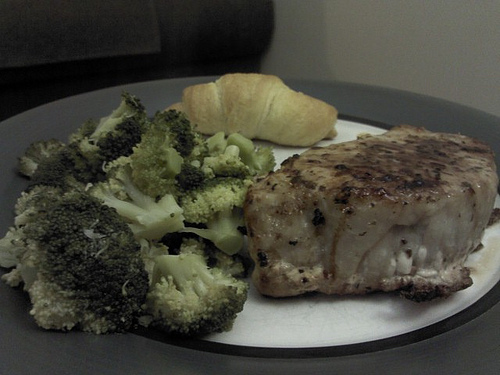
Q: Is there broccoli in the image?
A: Yes, there is broccoli.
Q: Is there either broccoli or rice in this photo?
A: Yes, there is broccoli.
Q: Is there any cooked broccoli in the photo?
A: Yes, there is cooked broccoli.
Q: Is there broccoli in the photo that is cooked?
A: Yes, there is broccoli that is cooked.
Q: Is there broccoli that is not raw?
A: Yes, there is cooked broccoli.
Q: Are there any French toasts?
A: No, there are no French toasts.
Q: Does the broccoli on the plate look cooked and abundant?
A: Yes, the broccoli is cooked and abundant.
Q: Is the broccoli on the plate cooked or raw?
A: The broccoli is cooked.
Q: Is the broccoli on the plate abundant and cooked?
A: Yes, the broccoli is abundant and cooked.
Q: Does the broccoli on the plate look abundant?
A: Yes, the broccoli is abundant.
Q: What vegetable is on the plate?
A: The vegetable is broccoli.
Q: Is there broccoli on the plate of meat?
A: Yes, there is broccoli on the plate.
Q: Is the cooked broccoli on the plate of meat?
A: Yes, the broccoli is on the plate.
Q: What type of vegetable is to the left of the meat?
A: The vegetable is broccoli.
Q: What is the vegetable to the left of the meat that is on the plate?
A: The vegetable is broccoli.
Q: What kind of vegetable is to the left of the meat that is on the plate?
A: The vegetable is broccoli.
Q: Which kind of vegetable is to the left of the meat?
A: The vegetable is broccoli.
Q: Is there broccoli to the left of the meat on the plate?
A: Yes, there is broccoli to the left of the meat.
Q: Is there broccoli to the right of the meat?
A: No, the broccoli is to the left of the meat.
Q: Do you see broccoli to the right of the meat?
A: No, the broccoli is to the left of the meat.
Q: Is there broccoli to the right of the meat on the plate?
A: No, the broccoli is to the left of the meat.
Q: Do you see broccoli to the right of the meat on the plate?
A: No, the broccoli is to the left of the meat.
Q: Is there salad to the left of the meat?
A: No, there is broccoli to the left of the meat.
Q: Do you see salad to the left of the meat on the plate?
A: No, there is broccoli to the left of the meat.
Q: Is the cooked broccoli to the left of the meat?
A: Yes, the broccoli is to the left of the meat.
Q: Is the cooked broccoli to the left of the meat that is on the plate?
A: Yes, the broccoli is to the left of the meat.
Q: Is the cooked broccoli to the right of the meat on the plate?
A: No, the broccoli is to the left of the meat.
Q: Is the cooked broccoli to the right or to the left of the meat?
A: The broccoli is to the left of the meat.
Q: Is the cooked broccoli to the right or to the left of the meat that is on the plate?
A: The broccoli is to the left of the meat.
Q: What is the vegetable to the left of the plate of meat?
A: The vegetable is broccoli.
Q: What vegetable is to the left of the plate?
A: The vegetable is broccoli.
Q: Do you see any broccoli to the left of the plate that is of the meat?
A: Yes, there is broccoli to the left of the plate.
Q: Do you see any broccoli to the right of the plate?
A: No, the broccoli is to the left of the plate.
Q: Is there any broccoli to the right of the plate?
A: No, the broccoli is to the left of the plate.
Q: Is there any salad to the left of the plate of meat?
A: No, there is broccoli to the left of the plate.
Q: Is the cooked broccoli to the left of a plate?
A: Yes, the broccoli is to the left of a plate.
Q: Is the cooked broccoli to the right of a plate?
A: No, the broccoli is to the left of a plate.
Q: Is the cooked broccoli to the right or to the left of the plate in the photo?
A: The broccoli is to the left of the plate.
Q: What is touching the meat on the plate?
A: The broccoli is touching the meat.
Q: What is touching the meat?
A: The broccoli is touching the meat.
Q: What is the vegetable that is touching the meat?
A: The vegetable is broccoli.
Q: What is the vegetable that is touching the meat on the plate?
A: The vegetable is broccoli.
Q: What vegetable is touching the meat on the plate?
A: The vegetable is broccoli.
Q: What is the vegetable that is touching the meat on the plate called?
A: The vegetable is broccoli.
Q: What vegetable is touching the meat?
A: The vegetable is broccoli.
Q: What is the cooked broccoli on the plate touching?
A: The broccoli is touching the meat.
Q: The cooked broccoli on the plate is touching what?
A: The broccoli is touching the meat.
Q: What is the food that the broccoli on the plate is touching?
A: The food is meat.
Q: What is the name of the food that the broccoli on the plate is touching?
A: The food is meat.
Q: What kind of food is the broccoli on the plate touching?
A: The broccoli is touching the meat.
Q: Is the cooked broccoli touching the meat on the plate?
A: Yes, the broccoli is touching the meat.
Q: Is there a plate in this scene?
A: Yes, there is a plate.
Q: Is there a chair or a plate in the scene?
A: Yes, there is a plate.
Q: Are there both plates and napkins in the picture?
A: No, there is a plate but no napkins.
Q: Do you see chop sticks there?
A: No, there are no chop sticks.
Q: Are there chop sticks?
A: No, there are no chop sticks.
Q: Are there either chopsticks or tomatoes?
A: No, there are no chopsticks or tomatoes.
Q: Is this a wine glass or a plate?
A: This is a plate.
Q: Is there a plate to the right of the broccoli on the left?
A: Yes, there is a plate to the right of the broccoli.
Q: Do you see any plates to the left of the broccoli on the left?
A: No, the plate is to the right of the broccoli.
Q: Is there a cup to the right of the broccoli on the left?
A: No, there is a plate to the right of the broccoli.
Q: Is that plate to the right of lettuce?
A: No, the plate is to the right of the broccoli.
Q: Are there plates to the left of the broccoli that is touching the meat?
A: No, the plate is to the right of the broccoli.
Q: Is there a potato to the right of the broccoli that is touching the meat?
A: No, there is a plate to the right of the broccoli.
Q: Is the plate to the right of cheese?
A: No, the plate is to the right of the broccoli.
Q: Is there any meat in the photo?
A: Yes, there is meat.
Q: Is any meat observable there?
A: Yes, there is meat.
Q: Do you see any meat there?
A: Yes, there is meat.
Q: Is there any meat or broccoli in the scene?
A: Yes, there is meat.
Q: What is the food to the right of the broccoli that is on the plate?
A: The food is meat.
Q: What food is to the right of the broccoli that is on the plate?
A: The food is meat.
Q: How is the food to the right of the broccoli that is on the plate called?
A: The food is meat.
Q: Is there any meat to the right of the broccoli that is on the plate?
A: Yes, there is meat to the right of the broccoli.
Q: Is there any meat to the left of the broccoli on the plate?
A: No, the meat is to the right of the broccoli.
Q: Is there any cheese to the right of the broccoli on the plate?
A: No, there is meat to the right of the broccoli.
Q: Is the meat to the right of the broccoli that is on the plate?
A: Yes, the meat is to the right of the broccoli.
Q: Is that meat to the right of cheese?
A: No, the meat is to the right of the broccoli.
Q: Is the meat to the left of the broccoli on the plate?
A: No, the meat is to the right of the broccoli.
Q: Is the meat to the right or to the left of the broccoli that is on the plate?
A: The meat is to the right of the broccoli.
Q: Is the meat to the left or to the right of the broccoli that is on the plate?
A: The meat is to the right of the broccoli.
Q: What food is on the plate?
A: The food is meat.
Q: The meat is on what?
A: The meat is on the plate.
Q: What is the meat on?
A: The meat is on the plate.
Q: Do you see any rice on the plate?
A: No, there is meat on the plate.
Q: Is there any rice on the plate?
A: No, there is meat on the plate.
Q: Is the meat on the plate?
A: Yes, the meat is on the plate.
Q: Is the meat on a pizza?
A: No, the meat is on the plate.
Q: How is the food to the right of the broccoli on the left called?
A: The food is meat.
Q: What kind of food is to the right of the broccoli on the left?
A: The food is meat.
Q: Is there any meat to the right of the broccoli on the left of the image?
A: Yes, there is meat to the right of the broccoli.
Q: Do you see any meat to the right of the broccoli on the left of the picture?
A: Yes, there is meat to the right of the broccoli.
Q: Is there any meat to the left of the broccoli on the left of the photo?
A: No, the meat is to the right of the broccoli.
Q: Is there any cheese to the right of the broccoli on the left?
A: No, there is meat to the right of the broccoli.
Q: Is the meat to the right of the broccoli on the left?
A: Yes, the meat is to the right of the broccoli.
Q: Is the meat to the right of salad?
A: No, the meat is to the right of the broccoli.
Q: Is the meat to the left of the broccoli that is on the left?
A: No, the meat is to the right of the broccoli.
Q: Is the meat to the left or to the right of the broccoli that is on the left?
A: The meat is to the right of the broccoli.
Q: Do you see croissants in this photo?
A: Yes, there is a croissant.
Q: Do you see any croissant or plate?
A: Yes, there is a croissant.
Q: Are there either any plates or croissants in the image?
A: Yes, there is a croissant.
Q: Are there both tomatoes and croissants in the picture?
A: No, there is a croissant but no tomatoes.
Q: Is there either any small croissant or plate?
A: Yes, there is a small croissant.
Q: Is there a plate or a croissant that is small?
A: Yes, the croissant is small.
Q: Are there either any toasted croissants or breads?
A: Yes, there is a toasted croissant.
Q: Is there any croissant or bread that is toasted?
A: Yes, the croissant is toasted.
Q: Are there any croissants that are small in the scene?
A: Yes, there is a small croissant.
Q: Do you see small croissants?
A: Yes, there is a small croissant.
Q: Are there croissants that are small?
A: Yes, there is a croissant that is small.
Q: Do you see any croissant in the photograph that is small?
A: Yes, there is a croissant that is small.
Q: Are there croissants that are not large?
A: Yes, there is a small croissant.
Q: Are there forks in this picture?
A: No, there are no forks.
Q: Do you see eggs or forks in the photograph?
A: No, there are no forks or eggs.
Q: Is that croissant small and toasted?
A: Yes, the croissant is small and toasted.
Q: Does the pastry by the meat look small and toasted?
A: Yes, the croissant is small and toasted.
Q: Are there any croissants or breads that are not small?
A: No, there is a croissant but it is small.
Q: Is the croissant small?
A: Yes, the croissant is small.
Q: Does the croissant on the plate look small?
A: Yes, the croissant is small.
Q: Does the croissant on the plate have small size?
A: Yes, the croissant is small.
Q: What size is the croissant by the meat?
A: The croissant is small.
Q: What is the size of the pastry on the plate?
A: The croissant is small.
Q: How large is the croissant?
A: The croissant is small.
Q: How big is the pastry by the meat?
A: The croissant is small.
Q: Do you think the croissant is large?
A: No, the croissant is small.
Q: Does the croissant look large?
A: No, the croissant is small.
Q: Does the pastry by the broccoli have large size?
A: No, the croissant is small.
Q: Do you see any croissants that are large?
A: No, there is a croissant but it is small.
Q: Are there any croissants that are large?
A: No, there is a croissant but it is small.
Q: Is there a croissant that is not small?
A: No, there is a croissant but it is small.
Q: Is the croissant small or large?
A: The croissant is small.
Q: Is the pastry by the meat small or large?
A: The croissant is small.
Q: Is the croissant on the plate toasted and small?
A: Yes, the croissant is toasted and small.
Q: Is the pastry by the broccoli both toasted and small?
A: Yes, the croissant is toasted and small.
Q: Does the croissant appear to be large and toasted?
A: No, the croissant is toasted but small.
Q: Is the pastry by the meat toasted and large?
A: No, the croissant is toasted but small.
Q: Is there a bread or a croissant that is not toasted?
A: No, there is a croissant but it is toasted.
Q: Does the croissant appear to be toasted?
A: Yes, the croissant is toasted.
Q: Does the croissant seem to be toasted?
A: Yes, the croissant is toasted.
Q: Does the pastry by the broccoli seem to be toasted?
A: Yes, the croissant is toasted.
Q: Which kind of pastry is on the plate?
A: The pastry is a croissant.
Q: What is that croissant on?
A: The croissant is on the plate.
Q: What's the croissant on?
A: The croissant is on the plate.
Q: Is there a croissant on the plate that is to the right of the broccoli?
A: Yes, there is a croissant on the plate.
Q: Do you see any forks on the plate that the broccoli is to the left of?
A: No, there is a croissant on the plate.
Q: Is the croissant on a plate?
A: Yes, the croissant is on a plate.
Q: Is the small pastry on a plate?
A: Yes, the croissant is on a plate.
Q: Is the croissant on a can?
A: No, the croissant is on a plate.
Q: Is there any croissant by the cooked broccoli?
A: Yes, there is a croissant by the broccoli.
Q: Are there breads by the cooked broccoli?
A: No, there is a croissant by the broccoli.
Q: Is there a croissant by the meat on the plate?
A: Yes, there is a croissant by the meat.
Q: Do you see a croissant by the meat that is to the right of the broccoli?
A: Yes, there is a croissant by the meat.